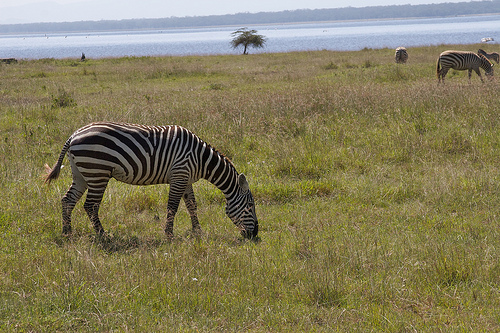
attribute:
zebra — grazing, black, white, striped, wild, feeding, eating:
[50, 120, 265, 242]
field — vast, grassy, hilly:
[11, 57, 497, 325]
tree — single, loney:
[232, 26, 261, 54]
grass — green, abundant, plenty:
[202, 73, 424, 157]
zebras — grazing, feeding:
[384, 39, 497, 96]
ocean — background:
[19, 10, 498, 61]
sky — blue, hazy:
[7, 1, 307, 22]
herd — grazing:
[29, 44, 496, 158]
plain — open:
[12, 66, 472, 158]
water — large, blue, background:
[41, 24, 419, 44]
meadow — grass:
[31, 56, 500, 223]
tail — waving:
[39, 134, 93, 175]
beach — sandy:
[18, 40, 483, 58]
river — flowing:
[17, 24, 500, 53]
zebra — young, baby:
[472, 45, 498, 62]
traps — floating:
[478, 34, 499, 47]